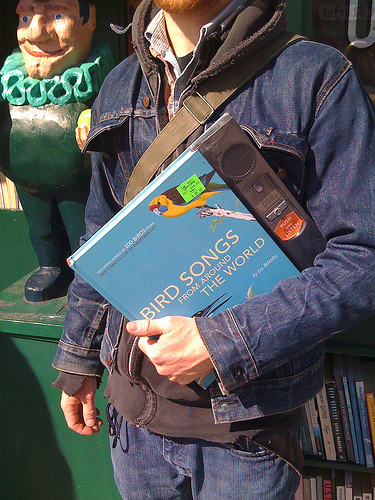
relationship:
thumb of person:
[125, 317, 164, 336] [56, 2, 374, 499]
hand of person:
[127, 314, 215, 387] [56, 2, 374, 499]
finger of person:
[58, 398, 96, 437] [56, 2, 374, 499]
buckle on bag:
[181, 91, 213, 123] [122, 34, 306, 210]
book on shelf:
[315, 384, 336, 462] [290, 321, 371, 498]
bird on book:
[146, 165, 235, 220] [65, 113, 326, 342]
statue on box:
[1, 1, 116, 302] [0, 264, 114, 496]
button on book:
[263, 199, 292, 223] [315, 384, 336, 462]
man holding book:
[56, 2, 374, 499] [65, 113, 326, 342]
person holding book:
[56, 2, 374, 499] [65, 113, 326, 342]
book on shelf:
[324, 372, 346, 461] [290, 321, 371, 498]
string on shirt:
[105, 403, 120, 441] [48, 1, 310, 446]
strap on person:
[122, 34, 306, 210] [56, 2, 374, 499]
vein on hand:
[177, 355, 208, 374] [127, 314, 215, 387]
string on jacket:
[105, 403, 120, 441] [57, 2, 374, 423]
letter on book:
[137, 305, 153, 320] [65, 113, 326, 342]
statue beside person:
[1, 1, 116, 302] [56, 2, 374, 499]